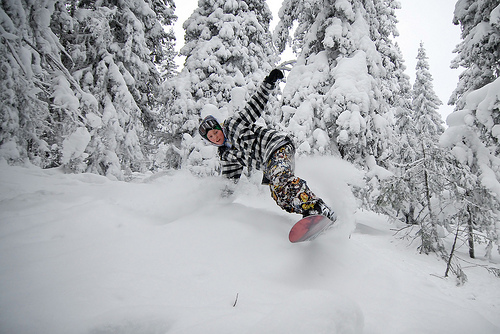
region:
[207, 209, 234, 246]
The snow is white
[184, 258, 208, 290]
The snow is white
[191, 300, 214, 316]
The snow is white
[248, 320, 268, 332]
The snow is white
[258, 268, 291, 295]
The snow is white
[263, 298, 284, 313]
The snow is white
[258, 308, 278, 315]
The snow is white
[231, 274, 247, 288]
The snow is white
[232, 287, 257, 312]
The snow is white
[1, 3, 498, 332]
an extraordinary amount of cold cold snow [at least to a californian]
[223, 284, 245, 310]
a lone twig emerges from snow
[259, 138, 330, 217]
'boarder pants are multi-color, multi-pattern, graffiti-ish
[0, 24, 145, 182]
branches everywhere, heavy, laden w/ snow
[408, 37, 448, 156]
a tall, snowed down evergreen in the far distance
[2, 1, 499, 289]
all trees are evergreen, only now they're white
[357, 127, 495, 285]
some bare branches of an ex-tree @ right, w/ snow on them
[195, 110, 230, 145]
hood over hat over head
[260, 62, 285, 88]
black glove w/ logo @ cuff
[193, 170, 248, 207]
one arm, one hand mussing up snow as 'boarder careens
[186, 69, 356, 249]
person snowboarding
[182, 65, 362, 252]
person leaning to the side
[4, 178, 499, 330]
perfect white snow with no footprints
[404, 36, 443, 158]
tall snow covered tree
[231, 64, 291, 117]
arm extended to the side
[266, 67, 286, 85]
black golve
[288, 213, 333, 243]
bottom of the snowboard is reddish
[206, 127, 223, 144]
not wearing goggles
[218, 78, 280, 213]
black and white jacket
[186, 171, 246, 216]
snow being kicked up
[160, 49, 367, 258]
the woman is snowboarding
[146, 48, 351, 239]
the sport of snowboarding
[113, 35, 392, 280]
she is snowboarding cross country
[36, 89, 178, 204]
the snow is very deep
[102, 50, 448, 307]
the snow is fresh powder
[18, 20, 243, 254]
the trees are covered in snow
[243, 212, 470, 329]
the snowboard is red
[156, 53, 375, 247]
she has goggles on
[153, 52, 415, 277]
she has a plaid jacket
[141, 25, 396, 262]
the jacket is black and white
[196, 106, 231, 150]
the head of a person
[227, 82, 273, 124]
the arm of a person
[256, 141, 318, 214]
the legs of a person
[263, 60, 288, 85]
the hand of a person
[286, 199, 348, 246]
a red snowboard under the person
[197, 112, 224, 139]
a pair of goggles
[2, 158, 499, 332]
white snow on the ground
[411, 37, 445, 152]
a snow covered tree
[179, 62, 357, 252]
a person on a snowboard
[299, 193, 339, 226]
a pair of snowboarding boots